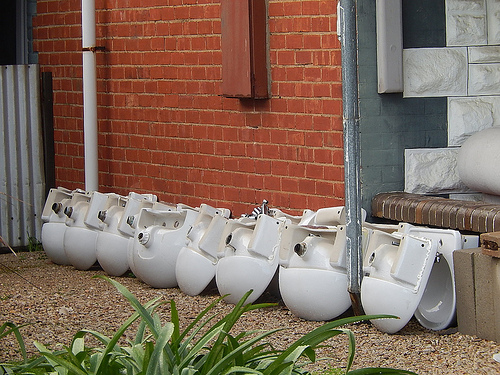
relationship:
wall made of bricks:
[31, 1, 346, 206] [156, 104, 300, 163]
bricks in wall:
[156, 104, 300, 163] [31, 1, 346, 206]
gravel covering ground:
[360, 335, 499, 370] [3, 231, 498, 373]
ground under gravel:
[3, 231, 498, 373] [360, 335, 499, 370]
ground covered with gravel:
[3, 231, 498, 373] [360, 335, 499, 370]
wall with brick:
[237, 85, 294, 142] [186, 119, 300, 185]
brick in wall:
[186, 119, 300, 185] [237, 85, 294, 142]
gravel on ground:
[4, 247, 498, 373] [3, 231, 498, 373]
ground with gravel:
[3, 231, 498, 373] [4, 247, 498, 373]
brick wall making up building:
[31, 2, 347, 216] [48, 26, 335, 175]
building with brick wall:
[48, 26, 335, 175] [31, 2, 347, 216]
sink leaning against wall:
[299, 223, 346, 306] [31, 1, 346, 206]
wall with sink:
[31, 1, 346, 206] [299, 223, 346, 306]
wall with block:
[25, 5, 351, 215] [400, 52, 471, 97]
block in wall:
[400, 52, 471, 97] [25, 5, 351, 215]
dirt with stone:
[5, 255, 137, 356] [46, 293, 77, 318]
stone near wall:
[46, 293, 77, 318] [56, 299, 74, 315]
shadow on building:
[40, 69, 58, 186] [5, 0, 498, 315]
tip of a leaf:
[94, 274, 115, 281] [93, 273, 157, 324]